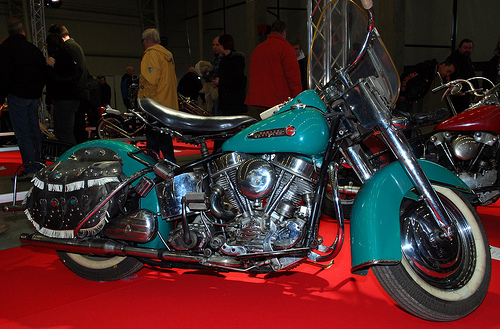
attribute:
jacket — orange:
[242, 31, 305, 111]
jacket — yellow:
[124, 38, 185, 103]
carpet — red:
[3, 138, 498, 328]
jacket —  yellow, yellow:
[137, 45, 179, 115]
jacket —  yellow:
[134, 45, 175, 114]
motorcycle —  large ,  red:
[318, 74, 498, 220]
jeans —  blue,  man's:
[5, 93, 46, 164]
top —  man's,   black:
[0, 33, 48, 97]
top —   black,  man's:
[0, 35, 43, 99]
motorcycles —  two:
[18, 2, 490, 319]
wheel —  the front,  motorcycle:
[348, 158, 490, 321]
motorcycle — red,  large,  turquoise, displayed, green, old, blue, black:
[7, 1, 484, 324]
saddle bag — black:
[11, 157, 126, 241]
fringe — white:
[27, 174, 122, 192]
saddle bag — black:
[22, 157, 129, 245]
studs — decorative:
[18, 198, 101, 225]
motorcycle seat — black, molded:
[138, 90, 252, 133]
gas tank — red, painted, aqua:
[223, 103, 328, 155]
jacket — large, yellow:
[138, 42, 177, 111]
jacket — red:
[241, 30, 302, 106]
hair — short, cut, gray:
[142, 26, 161, 45]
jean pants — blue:
[5, 92, 44, 167]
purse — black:
[51, 50, 78, 88]